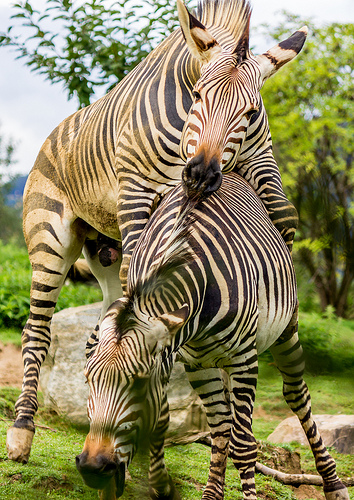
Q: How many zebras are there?
A: 2.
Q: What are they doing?
A: Mating.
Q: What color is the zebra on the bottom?
A: Black and white.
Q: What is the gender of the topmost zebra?
A: Male.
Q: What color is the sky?
A: Blue.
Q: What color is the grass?
A: Green.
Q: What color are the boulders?
A: Grey.